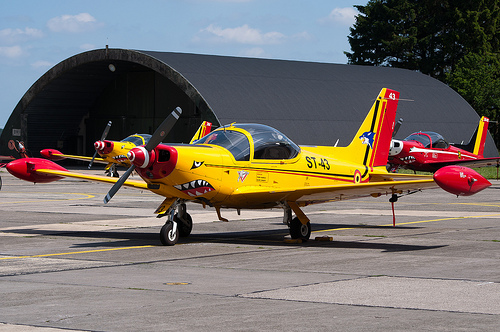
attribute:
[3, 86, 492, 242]
flights — small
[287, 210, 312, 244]
wheel — back, side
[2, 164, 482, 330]
runway — concrete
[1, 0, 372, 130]
sky — blue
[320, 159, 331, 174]
number — black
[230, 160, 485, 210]
wing — red, yellow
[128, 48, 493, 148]
roof — black